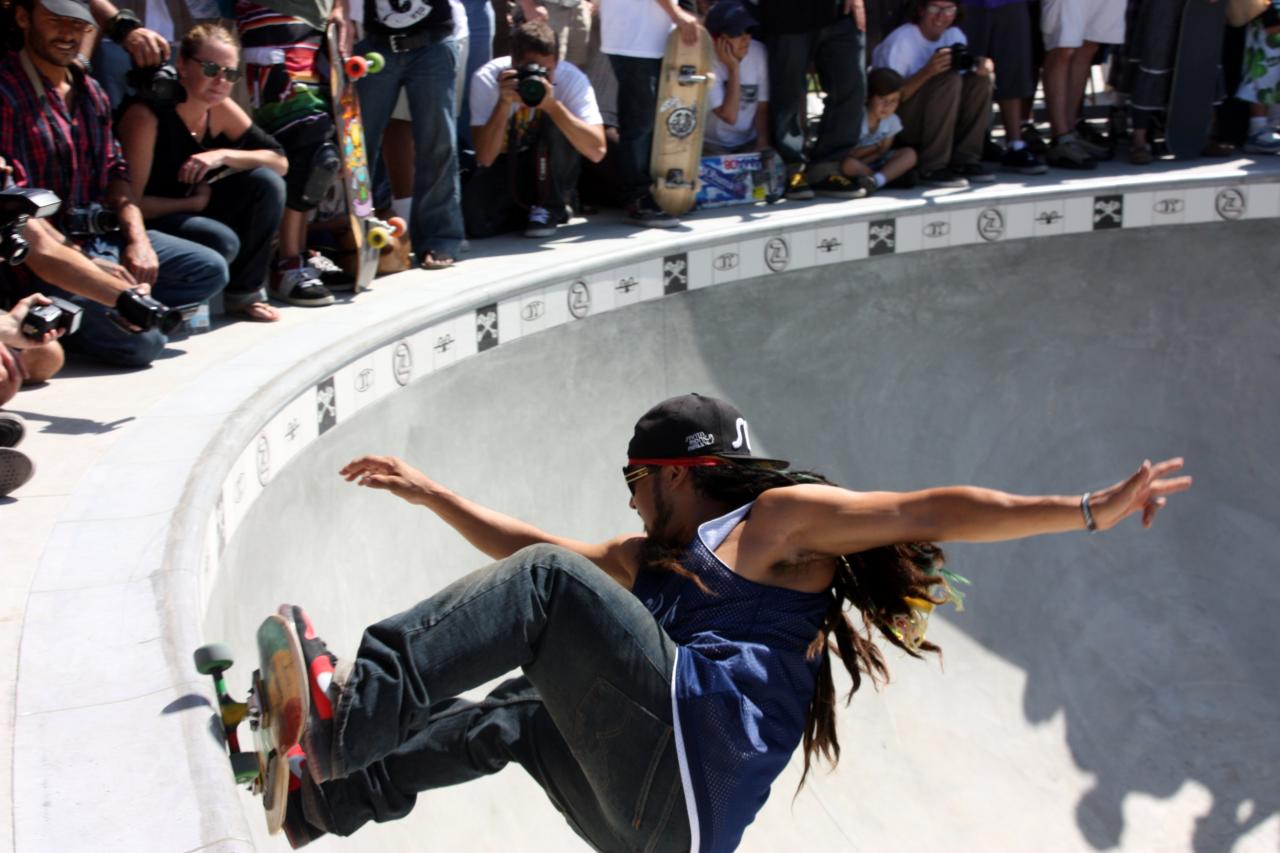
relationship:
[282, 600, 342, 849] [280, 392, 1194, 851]
part of a man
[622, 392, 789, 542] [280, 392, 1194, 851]
part of a man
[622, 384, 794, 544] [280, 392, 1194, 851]
part of a man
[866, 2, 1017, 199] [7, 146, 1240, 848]
person at a park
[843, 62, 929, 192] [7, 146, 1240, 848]
person at a park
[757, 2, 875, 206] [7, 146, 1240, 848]
person at a park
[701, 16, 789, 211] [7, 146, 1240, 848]
person at a park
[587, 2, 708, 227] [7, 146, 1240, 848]
person at a park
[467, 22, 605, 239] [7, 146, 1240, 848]
man at a park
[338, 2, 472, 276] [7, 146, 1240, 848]
person at a park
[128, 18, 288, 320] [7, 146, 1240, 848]
woman at a park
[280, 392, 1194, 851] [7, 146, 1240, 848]
man at a park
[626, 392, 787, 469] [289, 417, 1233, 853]
cap cap on a man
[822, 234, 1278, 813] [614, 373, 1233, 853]
shadow in a skate ramp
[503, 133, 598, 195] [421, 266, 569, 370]
man taking photos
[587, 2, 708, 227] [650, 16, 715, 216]
person holding wood skateboard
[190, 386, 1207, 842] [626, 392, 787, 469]
man in cap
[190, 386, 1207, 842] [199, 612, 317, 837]
man riding skateboard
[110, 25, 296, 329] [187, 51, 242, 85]
woman in black sunglasses